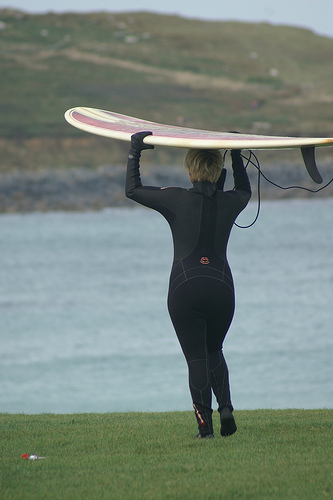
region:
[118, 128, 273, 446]
this is a lady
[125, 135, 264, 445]
the lady is in a black swim suit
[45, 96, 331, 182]
the lady is carrying a surf board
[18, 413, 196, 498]
grass on the ground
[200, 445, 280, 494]
grass on the ground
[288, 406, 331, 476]
grass on the ground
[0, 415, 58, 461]
grass on the ground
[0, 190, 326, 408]
the water is blue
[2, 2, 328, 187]
a small hill in the distance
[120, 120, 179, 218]
this is a hand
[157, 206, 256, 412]
the swimsuit is tight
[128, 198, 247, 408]
the swim is black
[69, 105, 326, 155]
the surfboard is on the head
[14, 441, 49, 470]
object is on the ground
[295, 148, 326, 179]
the fin is black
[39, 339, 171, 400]
the water is black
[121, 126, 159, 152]
the gloves are black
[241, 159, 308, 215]
the string is attached to the board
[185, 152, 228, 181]
the hair is brown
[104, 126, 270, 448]
the gender of the person is female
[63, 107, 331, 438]
Surfer walking towards water in wet suit.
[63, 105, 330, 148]
short board that is white with red horizontal stripes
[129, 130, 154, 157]
left handed black glove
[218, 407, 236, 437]
water shoes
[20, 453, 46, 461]
unidentified silver and red item in the grass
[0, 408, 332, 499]
plush green grass that the woman is standing on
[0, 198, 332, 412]
water spanning over a majority of the photo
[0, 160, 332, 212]
blurry wall of rocks at the shoreline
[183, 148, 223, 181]
blonde head belonging to a female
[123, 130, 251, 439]
woman in a full body wetsuit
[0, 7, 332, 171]
grassy and rocky hill with a lot of seagulls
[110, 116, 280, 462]
a person walking on grass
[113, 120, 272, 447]
a surfer in a black wet suit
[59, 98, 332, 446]
a person holding a surfboard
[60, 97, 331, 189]
a white and red surfboard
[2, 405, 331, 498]
a green grass field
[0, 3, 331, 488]
a scene outside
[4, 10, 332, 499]
a scene happening during the day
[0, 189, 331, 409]
a blue ocean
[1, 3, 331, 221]
a hill in background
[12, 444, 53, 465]
something that is white and red in the grass